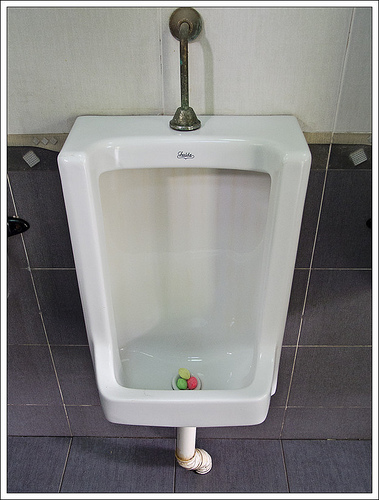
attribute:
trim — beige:
[7, 129, 66, 149]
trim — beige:
[307, 132, 369, 144]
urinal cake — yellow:
[177, 363, 189, 378]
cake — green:
[174, 374, 187, 388]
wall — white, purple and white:
[8, 7, 371, 439]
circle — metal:
[166, 4, 203, 42]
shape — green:
[176, 377, 188, 390]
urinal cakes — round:
[178, 369, 190, 379]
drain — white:
[169, 365, 213, 476]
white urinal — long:
[56, 112, 314, 432]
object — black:
[7, 214, 30, 239]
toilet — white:
[52, 116, 322, 351]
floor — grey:
[8, 437, 370, 493]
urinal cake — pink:
[167, 363, 211, 391]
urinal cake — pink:
[177, 378, 186, 392]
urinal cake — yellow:
[187, 377, 195, 386]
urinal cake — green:
[179, 370, 189, 378]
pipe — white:
[172, 425, 218, 476]